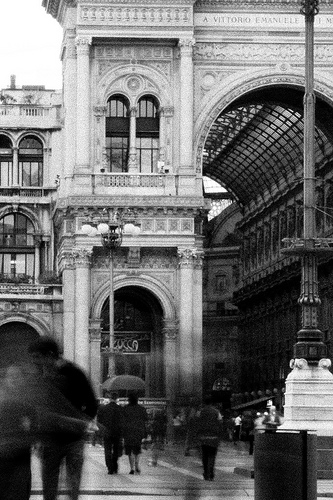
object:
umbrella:
[102, 372, 146, 391]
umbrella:
[79, 218, 195, 245]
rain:
[35, 148, 260, 421]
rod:
[116, 397, 130, 402]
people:
[0, 335, 257, 500]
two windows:
[105, 92, 160, 173]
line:
[148, 459, 205, 481]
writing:
[203, 16, 328, 23]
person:
[195, 389, 223, 481]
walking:
[203, 468, 216, 480]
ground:
[31, 441, 253, 500]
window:
[15, 253, 34, 277]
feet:
[108, 468, 141, 475]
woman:
[119, 392, 148, 474]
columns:
[63, 244, 205, 398]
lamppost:
[103, 248, 119, 378]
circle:
[81, 223, 140, 237]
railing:
[109, 173, 162, 187]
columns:
[74, 39, 193, 196]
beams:
[201, 83, 333, 201]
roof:
[200, 0, 333, 9]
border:
[235, 253, 291, 291]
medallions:
[234, 176, 304, 277]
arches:
[0, 128, 43, 288]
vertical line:
[25, 220, 27, 276]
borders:
[193, 44, 333, 59]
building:
[0, 0, 333, 438]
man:
[97, 393, 123, 475]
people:
[96, 393, 148, 475]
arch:
[100, 285, 165, 402]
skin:
[128, 452, 139, 468]